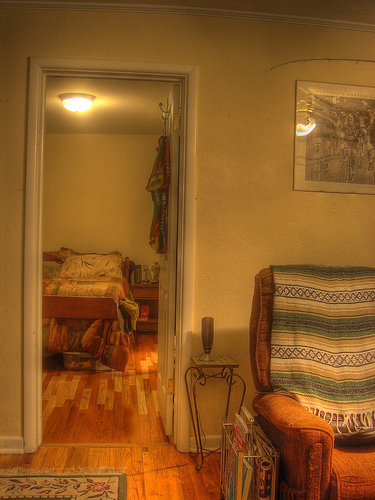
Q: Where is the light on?
A: Bedroom.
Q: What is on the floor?
A: Rug.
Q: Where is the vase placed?
A: Table.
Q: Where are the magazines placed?
A: Rack.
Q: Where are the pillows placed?
A: Bed.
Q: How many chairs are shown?
A: One.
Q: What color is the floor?
A: Brown.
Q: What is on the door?
A: Robe.